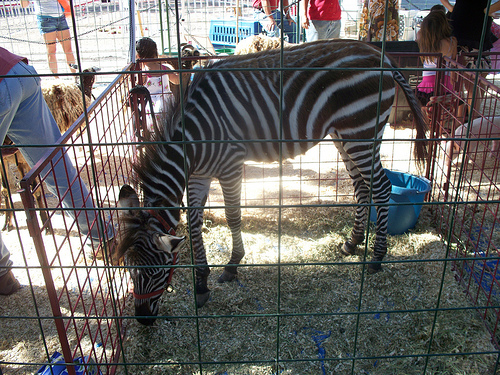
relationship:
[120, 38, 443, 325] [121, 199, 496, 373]
zebra eating grain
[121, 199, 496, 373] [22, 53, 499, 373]
grain on bottom of cage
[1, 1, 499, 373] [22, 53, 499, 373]
wiring attached to cage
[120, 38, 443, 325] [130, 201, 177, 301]
zebra wearing halter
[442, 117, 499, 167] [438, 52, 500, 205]
pig inside cage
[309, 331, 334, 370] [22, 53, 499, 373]
tarp on bottom of cage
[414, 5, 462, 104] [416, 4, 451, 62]
girl has hair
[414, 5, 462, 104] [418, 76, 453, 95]
girl wearing skirt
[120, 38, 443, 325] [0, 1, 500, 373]
zebra inside petting zoo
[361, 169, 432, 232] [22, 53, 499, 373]
bucket inside cage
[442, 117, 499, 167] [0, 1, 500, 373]
pig inside petting zoo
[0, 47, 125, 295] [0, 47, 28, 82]
person wearing shirt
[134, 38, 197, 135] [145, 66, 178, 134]
girl wearing dress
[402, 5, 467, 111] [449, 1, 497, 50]
girl wearing top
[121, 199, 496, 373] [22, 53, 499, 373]
grain inside cage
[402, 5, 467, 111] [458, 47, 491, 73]
girl wearing shorts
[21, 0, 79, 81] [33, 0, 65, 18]
woman wearing shirt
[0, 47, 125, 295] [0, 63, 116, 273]
person wearing jeans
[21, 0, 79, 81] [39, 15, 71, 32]
woman wearing shorts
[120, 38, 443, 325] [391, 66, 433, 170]
zebra has tail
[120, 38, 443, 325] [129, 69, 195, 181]
zebra has mane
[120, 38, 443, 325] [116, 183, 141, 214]
zebra has ear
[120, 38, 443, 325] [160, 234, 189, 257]
zebra has ear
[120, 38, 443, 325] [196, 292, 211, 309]
zebra has hoof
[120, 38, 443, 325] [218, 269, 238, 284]
zebra has hoof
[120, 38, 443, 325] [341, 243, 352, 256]
zebra has hoof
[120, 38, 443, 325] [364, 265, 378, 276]
zebra has hoof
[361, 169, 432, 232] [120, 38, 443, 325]
bucket near zebra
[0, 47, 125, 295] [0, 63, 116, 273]
man wearing jeans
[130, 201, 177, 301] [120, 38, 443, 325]
halter worn by zebra